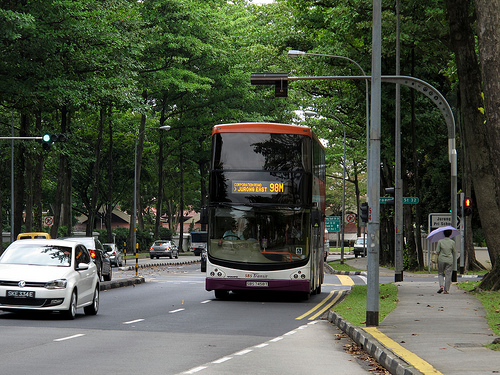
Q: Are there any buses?
A: Yes, there is a bus.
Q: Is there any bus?
A: Yes, there is a bus.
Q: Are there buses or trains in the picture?
A: Yes, there is a bus.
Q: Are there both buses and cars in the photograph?
A: Yes, there are both a bus and a car.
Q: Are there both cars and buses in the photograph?
A: Yes, there are both a bus and a car.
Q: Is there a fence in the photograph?
A: No, there are no fences.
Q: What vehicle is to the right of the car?
A: The vehicle is a bus.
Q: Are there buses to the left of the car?
A: No, the bus is to the right of the car.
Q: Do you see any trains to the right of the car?
A: No, there is a bus to the right of the car.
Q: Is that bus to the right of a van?
A: No, the bus is to the right of a car.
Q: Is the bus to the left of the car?
A: No, the bus is to the right of the car.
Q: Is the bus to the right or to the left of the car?
A: The bus is to the right of the car.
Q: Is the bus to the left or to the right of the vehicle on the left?
A: The bus is to the right of the car.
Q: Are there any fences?
A: No, there are no fences.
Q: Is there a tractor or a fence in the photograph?
A: No, there are no fences or tractors.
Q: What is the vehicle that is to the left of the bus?
A: The vehicle is a car.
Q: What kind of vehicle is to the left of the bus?
A: The vehicle is a car.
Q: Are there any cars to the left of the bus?
A: Yes, there is a car to the left of the bus.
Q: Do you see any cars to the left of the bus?
A: Yes, there is a car to the left of the bus.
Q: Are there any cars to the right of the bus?
A: No, the car is to the left of the bus.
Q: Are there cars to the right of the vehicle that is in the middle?
A: No, the car is to the left of the bus.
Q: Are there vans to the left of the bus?
A: No, there is a car to the left of the bus.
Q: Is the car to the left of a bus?
A: Yes, the car is to the left of a bus.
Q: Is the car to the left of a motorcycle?
A: No, the car is to the left of a bus.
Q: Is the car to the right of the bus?
A: No, the car is to the left of the bus.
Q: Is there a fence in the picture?
A: No, there are no fences.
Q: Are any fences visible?
A: No, there are no fences.